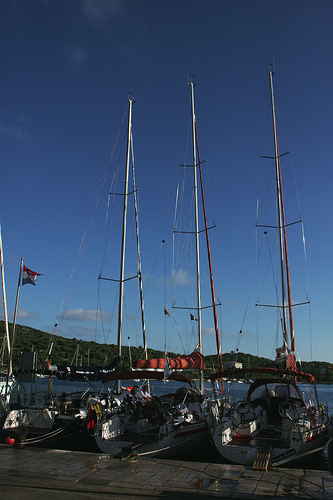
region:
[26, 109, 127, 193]
The sky is blue and clear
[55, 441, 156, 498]
The dock is wooden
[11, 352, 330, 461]
The boats are together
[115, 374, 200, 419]
People are on the boats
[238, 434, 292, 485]
A ramp is coming from the boat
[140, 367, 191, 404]
The water is calm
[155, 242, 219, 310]
The cloud is in the sky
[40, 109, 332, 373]
The sails are tall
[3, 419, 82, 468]
The boat is tied up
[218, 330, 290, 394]
Trees are in the back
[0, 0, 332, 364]
a large area of blue sky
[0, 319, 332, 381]
a large wooded area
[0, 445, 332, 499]
a dock on the water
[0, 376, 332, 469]
a large body of blue water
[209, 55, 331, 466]
a sailboat on the water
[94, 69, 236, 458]
a sailboat on the water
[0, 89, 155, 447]
a sailboat on the water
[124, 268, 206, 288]
a group of clouds in the sky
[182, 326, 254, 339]
a group of clouds in the sky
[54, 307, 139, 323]
a group of clouds in the sky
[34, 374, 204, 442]
boat in harbor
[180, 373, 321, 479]
boat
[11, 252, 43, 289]
flag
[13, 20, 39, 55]
white clouds in blue sky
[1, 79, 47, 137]
white clouds in blue sky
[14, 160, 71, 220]
white clouds in blue sky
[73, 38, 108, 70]
white clouds in blue sky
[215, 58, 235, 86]
white clouds in blue sky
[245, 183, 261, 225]
white clouds in blue sky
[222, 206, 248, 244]
white clouds in blue sky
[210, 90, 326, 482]
the boat at the marina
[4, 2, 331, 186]
the sky is blue and clear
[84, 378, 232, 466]
the boat at the marina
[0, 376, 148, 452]
the boat at the marina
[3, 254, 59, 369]
flag on the flag pole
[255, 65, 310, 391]
the mast on the boat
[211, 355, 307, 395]
the sail on the mast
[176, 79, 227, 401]
mast on the boat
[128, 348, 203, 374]
the sail on the mast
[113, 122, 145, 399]
mast on the boat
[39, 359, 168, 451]
boat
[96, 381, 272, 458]
boats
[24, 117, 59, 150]
white clouds in blues sky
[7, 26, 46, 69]
white clouds in blues sky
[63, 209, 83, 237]
white clouds in blues sky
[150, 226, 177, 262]
white clouds in blues sky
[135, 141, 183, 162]
white clouds in blues sky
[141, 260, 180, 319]
white clouds in blues sky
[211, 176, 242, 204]
white clouds in blues sky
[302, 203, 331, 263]
white clouds in blues sky